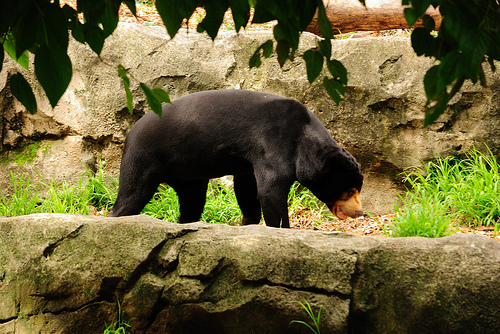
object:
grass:
[390, 140, 498, 236]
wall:
[4, 214, 98, 332]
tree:
[0, 0, 173, 118]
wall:
[0, 25, 500, 217]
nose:
[344, 201, 362, 218]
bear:
[110, 89, 367, 229]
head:
[294, 118, 367, 222]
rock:
[149, 232, 404, 306]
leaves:
[400, 0, 500, 131]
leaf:
[309, 65, 362, 110]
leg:
[252, 157, 292, 228]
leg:
[232, 172, 262, 226]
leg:
[111, 131, 175, 216]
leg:
[162, 181, 206, 225]